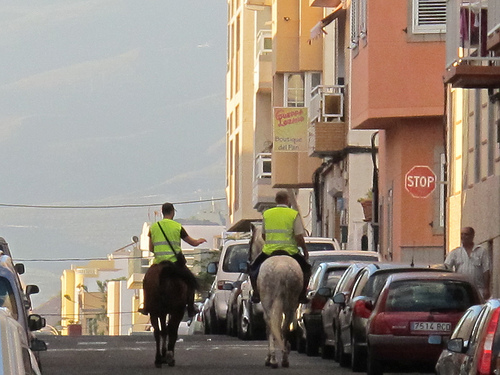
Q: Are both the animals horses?
A: Yes, all the animals are horses.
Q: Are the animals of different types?
A: No, all the animals are horses.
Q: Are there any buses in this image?
A: No, there are no buses.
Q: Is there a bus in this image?
A: No, there are no buses.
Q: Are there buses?
A: No, there are no buses.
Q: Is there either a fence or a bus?
A: No, there are no buses or fences.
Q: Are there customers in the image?
A: No, there are no customers.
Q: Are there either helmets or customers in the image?
A: No, there are no customers or helmets.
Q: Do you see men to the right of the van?
A: Yes, there is a man to the right of the van.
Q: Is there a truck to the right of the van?
A: No, there is a man to the right of the van.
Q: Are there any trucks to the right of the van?
A: No, there is a man to the right of the van.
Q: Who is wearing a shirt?
A: The man is wearing a shirt.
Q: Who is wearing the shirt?
A: The man is wearing a shirt.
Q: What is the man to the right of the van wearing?
A: The man is wearing a shirt.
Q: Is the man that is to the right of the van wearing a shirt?
A: Yes, the man is wearing a shirt.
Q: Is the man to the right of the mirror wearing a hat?
A: No, the man is wearing a shirt.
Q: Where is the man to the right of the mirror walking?
A: The man is walking on the sidewalk.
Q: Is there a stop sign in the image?
A: Yes, there is a stop sign.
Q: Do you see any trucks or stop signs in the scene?
A: Yes, there is a stop sign.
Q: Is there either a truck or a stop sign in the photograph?
A: Yes, there is a stop sign.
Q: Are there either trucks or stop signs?
A: Yes, there is a stop sign.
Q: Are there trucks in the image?
A: No, there are no trucks.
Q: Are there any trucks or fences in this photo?
A: No, there are no trucks or fences.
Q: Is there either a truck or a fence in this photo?
A: No, there are no trucks or fences.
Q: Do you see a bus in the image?
A: No, there are no buses.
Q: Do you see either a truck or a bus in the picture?
A: No, there are no buses or trucks.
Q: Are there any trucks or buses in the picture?
A: No, there are no buses or trucks.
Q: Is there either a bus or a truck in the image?
A: No, there are no buses or trucks.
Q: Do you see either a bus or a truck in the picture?
A: No, there are no buses or trucks.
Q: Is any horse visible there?
A: Yes, there is a horse.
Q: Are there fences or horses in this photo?
A: Yes, there is a horse.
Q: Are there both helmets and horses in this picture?
A: No, there is a horse but no helmets.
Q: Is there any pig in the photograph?
A: No, there are no pigs.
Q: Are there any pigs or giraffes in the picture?
A: No, there are no pigs or giraffes.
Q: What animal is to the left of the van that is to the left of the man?
A: The animal is a horse.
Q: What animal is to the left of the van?
A: The animal is a horse.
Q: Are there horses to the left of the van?
A: Yes, there is a horse to the left of the van.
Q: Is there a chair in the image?
A: No, there are no chairs.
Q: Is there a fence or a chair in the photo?
A: No, there are no chairs or fences.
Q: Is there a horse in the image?
A: Yes, there is a horse.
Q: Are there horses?
A: Yes, there is a horse.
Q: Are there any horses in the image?
A: Yes, there is a horse.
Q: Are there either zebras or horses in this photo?
A: Yes, there is a horse.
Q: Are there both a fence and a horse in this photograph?
A: No, there is a horse but no fences.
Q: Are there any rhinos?
A: No, there are no rhinos.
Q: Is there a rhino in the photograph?
A: No, there are no rhinos.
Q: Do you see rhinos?
A: No, there are no rhinos.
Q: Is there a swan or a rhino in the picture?
A: No, there are no rhinos or swans.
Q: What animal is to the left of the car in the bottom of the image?
A: The animal is a horse.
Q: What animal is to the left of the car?
A: The animal is a horse.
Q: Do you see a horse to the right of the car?
A: No, the horse is to the left of the car.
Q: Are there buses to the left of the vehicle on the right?
A: No, there is a horse to the left of the car.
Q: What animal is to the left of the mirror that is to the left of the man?
A: The animal is a horse.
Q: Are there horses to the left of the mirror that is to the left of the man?
A: Yes, there is a horse to the left of the mirror.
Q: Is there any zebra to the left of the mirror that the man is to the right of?
A: No, there is a horse to the left of the mirror.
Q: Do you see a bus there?
A: No, there are no buses.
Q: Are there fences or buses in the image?
A: No, there are no buses or fences.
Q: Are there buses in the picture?
A: No, there are no buses.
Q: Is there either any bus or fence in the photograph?
A: No, there are no buses or fences.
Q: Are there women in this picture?
A: No, there are no women.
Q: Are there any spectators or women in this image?
A: No, there are no women or spectators.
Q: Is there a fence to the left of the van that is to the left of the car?
A: No, there is a man to the left of the van.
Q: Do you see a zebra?
A: No, there are no zebras.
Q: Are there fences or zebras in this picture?
A: No, there are no zebras or fences.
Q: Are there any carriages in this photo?
A: No, there are no carriages.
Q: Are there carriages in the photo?
A: No, there are no carriages.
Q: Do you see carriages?
A: No, there are no carriages.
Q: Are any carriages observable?
A: No, there are no carriages.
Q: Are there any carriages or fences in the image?
A: No, there are no carriages or fences.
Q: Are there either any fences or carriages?
A: No, there are no carriages or fences.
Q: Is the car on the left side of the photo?
A: No, the car is on the right of the image.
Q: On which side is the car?
A: The car is on the right of the image.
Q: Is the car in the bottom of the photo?
A: Yes, the car is in the bottom of the image.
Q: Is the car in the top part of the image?
A: No, the car is in the bottom of the image.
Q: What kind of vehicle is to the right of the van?
A: The vehicle is a car.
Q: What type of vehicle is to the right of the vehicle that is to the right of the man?
A: The vehicle is a car.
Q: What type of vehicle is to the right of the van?
A: The vehicle is a car.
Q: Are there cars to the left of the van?
A: No, the car is to the right of the van.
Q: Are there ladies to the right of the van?
A: No, there is a car to the right of the van.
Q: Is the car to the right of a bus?
A: No, the car is to the right of a van.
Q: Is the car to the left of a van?
A: No, the car is to the right of a van.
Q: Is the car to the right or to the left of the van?
A: The car is to the right of the van.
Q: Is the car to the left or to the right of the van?
A: The car is to the right of the van.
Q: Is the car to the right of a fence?
A: No, the car is to the right of a horse.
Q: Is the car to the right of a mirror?
A: Yes, the car is to the right of a mirror.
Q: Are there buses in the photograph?
A: No, there are no buses.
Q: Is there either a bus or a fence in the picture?
A: No, there are no buses or fences.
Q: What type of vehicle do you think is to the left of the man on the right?
A: The vehicle is a van.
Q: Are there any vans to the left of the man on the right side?
A: Yes, there is a van to the left of the man.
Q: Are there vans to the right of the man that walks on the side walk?
A: No, the van is to the left of the man.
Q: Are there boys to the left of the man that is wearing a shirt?
A: No, there is a van to the left of the man.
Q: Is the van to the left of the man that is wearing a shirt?
A: Yes, the van is to the left of the man.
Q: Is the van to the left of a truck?
A: No, the van is to the left of the man.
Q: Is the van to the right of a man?
A: No, the van is to the left of a man.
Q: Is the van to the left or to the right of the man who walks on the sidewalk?
A: The van is to the left of the man.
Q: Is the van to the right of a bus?
A: No, the van is to the right of a man.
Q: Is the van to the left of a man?
A: No, the van is to the right of a man.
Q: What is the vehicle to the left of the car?
A: The vehicle is a van.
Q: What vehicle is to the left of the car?
A: The vehicle is a van.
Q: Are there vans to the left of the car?
A: Yes, there is a van to the left of the car.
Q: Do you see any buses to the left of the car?
A: No, there is a van to the left of the car.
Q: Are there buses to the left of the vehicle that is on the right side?
A: No, there is a van to the left of the car.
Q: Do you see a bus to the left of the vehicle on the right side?
A: No, there is a van to the left of the car.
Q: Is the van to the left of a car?
A: Yes, the van is to the left of a car.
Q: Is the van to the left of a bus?
A: No, the van is to the left of a car.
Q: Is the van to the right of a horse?
A: Yes, the van is to the right of a horse.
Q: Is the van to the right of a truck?
A: No, the van is to the right of a horse.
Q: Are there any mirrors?
A: Yes, there is a mirror.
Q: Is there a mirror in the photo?
A: Yes, there is a mirror.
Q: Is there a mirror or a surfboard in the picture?
A: Yes, there is a mirror.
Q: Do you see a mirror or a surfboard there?
A: Yes, there is a mirror.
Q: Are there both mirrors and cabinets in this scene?
A: No, there is a mirror but no cabinets.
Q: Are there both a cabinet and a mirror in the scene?
A: No, there is a mirror but no cabinets.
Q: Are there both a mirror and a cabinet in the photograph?
A: No, there is a mirror but no cabinets.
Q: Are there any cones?
A: No, there are no cones.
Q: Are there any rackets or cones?
A: No, there are no cones or rackets.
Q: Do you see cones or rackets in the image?
A: No, there are no cones or rackets.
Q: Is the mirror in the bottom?
A: Yes, the mirror is in the bottom of the image.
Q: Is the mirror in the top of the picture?
A: No, the mirror is in the bottom of the image.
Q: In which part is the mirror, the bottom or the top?
A: The mirror is in the bottom of the image.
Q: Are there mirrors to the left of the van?
A: No, the mirror is to the right of the van.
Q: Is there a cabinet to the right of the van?
A: No, there is a mirror to the right of the van.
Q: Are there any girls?
A: No, there are no girls.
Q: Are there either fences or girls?
A: No, there are no girls or fences.